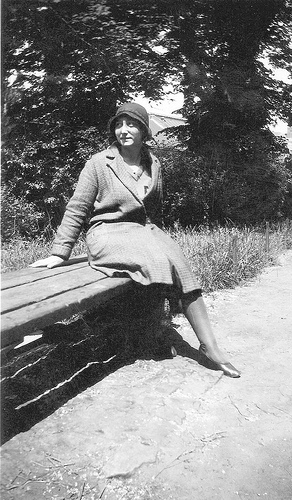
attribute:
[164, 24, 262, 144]
trees —  in black and white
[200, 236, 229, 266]
grass —  in black and white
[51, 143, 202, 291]
long jacket — winter